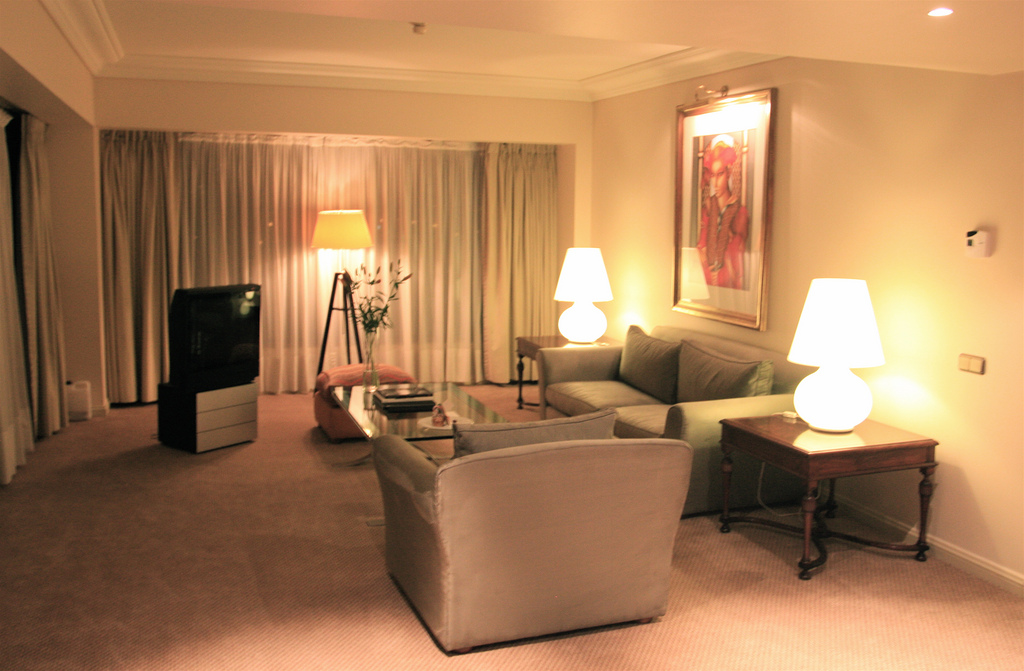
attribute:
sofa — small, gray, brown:
[574, 319, 747, 440]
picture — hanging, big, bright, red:
[662, 101, 780, 346]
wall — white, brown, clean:
[805, 99, 936, 245]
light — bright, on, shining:
[542, 235, 658, 395]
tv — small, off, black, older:
[161, 273, 283, 392]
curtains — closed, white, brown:
[227, 140, 487, 215]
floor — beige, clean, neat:
[91, 486, 384, 638]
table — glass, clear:
[348, 380, 485, 457]